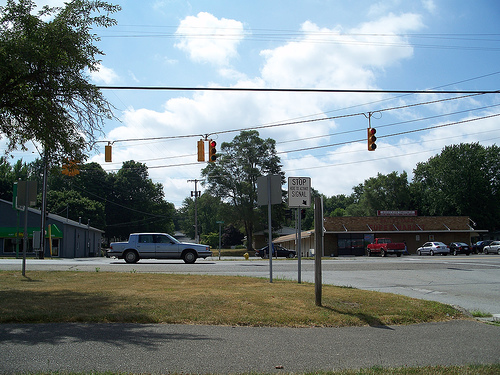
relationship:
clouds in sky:
[83, 12, 445, 185] [2, 4, 498, 215]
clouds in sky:
[80, 0, 500, 210] [119, 42, 172, 74]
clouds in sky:
[80, 0, 500, 210] [2, 4, 498, 215]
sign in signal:
[288, 175, 310, 207] [105, 127, 377, 161]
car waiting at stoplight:
[105, 232, 212, 263] [356, 105, 393, 172]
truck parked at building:
[365, 236, 407, 256] [271, 210, 489, 258]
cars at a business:
[151, 166, 498, 292] [309, 202, 483, 262]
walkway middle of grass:
[7, 324, 499, 364] [1, 266, 479, 326]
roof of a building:
[322, 198, 488, 233] [287, 164, 497, 273]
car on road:
[107, 232, 213, 263] [1, 234, 497, 326]